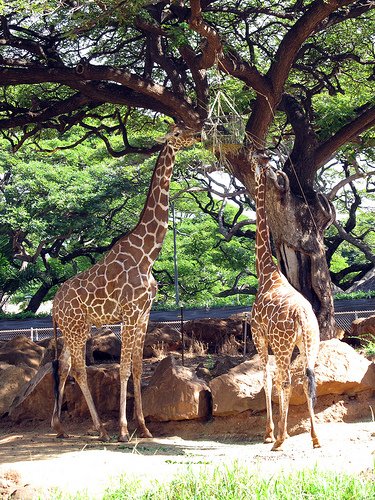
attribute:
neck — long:
[95, 147, 179, 266]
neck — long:
[254, 176, 293, 287]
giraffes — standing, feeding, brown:
[41, 123, 328, 452]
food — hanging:
[187, 79, 248, 175]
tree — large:
[4, 4, 375, 347]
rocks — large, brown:
[0, 313, 374, 432]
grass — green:
[33, 456, 374, 497]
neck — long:
[245, 173, 278, 278]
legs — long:
[42, 316, 162, 440]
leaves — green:
[0, 112, 169, 259]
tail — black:
[306, 366, 320, 398]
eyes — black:
[171, 127, 183, 141]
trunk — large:
[214, 149, 341, 341]